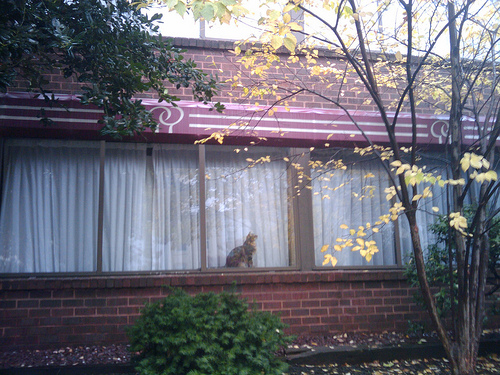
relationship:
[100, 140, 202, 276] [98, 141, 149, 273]
window has curtain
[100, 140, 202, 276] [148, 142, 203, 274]
window has curtain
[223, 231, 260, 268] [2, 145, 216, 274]
cat on window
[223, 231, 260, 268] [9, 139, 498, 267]
cat on window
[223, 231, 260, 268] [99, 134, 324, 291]
cat in window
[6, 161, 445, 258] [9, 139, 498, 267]
curtains on window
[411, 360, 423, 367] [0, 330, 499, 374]
leaves on ground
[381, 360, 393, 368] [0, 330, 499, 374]
leaves on ground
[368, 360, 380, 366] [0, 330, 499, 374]
leaves on ground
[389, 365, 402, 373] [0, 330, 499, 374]
leaves on ground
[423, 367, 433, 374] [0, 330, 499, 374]
leaves on ground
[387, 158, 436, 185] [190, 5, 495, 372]
leaves on tree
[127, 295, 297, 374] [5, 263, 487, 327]
bush near sidewalk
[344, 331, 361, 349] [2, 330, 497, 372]
leaf on sidewalk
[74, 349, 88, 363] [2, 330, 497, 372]
leaf on sidewalk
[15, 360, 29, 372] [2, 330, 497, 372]
leaf on sidewalk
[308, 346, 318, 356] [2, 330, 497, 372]
leaf on sidewalk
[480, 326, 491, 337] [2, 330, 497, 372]
leaf on sidewalk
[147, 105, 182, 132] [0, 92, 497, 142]
design on roof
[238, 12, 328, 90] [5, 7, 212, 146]
leaves on tree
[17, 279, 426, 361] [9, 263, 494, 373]
red bricks in wall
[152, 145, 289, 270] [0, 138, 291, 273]
curtain on window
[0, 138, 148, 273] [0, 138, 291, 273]
curtain on window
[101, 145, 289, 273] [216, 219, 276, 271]
curtain behind cat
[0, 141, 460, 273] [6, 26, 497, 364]
windows on building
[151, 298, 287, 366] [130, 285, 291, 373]
leaves on bush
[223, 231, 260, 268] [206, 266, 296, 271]
cat on window sill